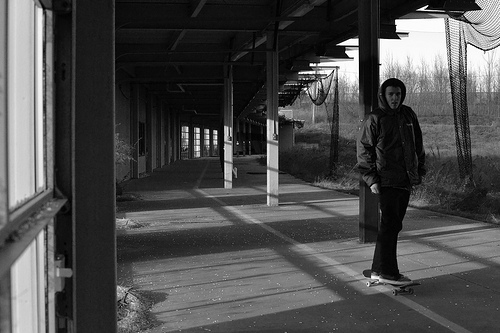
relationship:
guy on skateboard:
[353, 77, 428, 286] [357, 266, 424, 301]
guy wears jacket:
[353, 77, 428, 286] [349, 78, 426, 190]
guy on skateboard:
[353, 77, 428, 281] [353, 264, 416, 296]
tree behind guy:
[379, 51, 498, 117] [353, 77, 428, 286]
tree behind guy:
[487, 50, 488, 113] [353, 77, 428, 286]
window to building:
[180, 126, 189, 159] [1, 2, 484, 332]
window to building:
[192, 126, 201, 157] [1, 2, 484, 332]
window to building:
[201, 127, 211, 154] [1, 2, 484, 332]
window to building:
[212, 129, 219, 154] [1, 2, 484, 332]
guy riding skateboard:
[353, 77, 428, 286] [358, 241, 429, 312]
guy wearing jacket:
[353, 77, 428, 286] [357, 78, 428, 186]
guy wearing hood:
[353, 77, 428, 286] [377, 75, 407, 108]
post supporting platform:
[268, 39, 275, 115] [15, 0, 479, 130]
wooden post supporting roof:
[219, 58, 233, 188] [119, 0, 477, 132]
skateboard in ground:
[360, 267, 420, 296] [117, 153, 499, 331]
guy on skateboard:
[353, 77, 428, 286] [361, 269, 422, 296]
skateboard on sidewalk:
[361, 269, 422, 296] [175, 197, 499, 321]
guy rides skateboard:
[353, 77, 428, 286] [361, 268, 418, 295]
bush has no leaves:
[112, 127, 135, 173] [114, 123, 133, 223]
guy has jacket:
[353, 77, 428, 286] [355, 77, 426, 192]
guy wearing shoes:
[353, 77, 428, 286] [342, 239, 417, 289]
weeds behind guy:
[428, 140, 498, 218] [353, 77, 428, 281]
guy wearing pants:
[353, 77, 428, 286] [374, 178, 410, 277]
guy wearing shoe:
[353, 77, 428, 286] [370, 269, 405, 280]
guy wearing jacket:
[353, 77, 428, 286] [357, 106, 438, 196]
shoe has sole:
[375, 270, 421, 297] [374, 280, 417, 290]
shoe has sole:
[360, 260, 383, 290] [366, 274, 378, 284]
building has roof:
[1, 2, 484, 332] [119, 0, 477, 132]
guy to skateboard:
[353, 77, 428, 286] [357, 265, 424, 298]